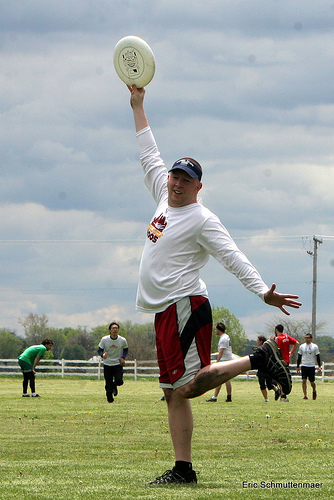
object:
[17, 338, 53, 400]
man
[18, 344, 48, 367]
shirt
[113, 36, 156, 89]
frisbee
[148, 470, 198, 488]
shoe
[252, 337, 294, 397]
shoe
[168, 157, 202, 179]
visor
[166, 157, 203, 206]
head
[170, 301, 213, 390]
shorts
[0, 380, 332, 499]
field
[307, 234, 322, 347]
pole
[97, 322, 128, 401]
man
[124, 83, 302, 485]
man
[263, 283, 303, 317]
hand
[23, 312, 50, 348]
tree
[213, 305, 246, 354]
tree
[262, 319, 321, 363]
tree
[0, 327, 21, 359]
tree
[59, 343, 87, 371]
tree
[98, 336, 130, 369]
shirt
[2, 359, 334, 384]
fence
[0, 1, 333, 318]
sky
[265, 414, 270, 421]
dandelion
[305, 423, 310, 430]
dandelion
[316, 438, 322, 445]
dandelion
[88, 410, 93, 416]
dandelion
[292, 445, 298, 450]
dandelion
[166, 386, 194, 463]
leg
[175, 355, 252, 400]
leg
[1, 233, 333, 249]
power lines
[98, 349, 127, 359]
shirt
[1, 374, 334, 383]
grass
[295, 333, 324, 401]
man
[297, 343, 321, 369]
shirt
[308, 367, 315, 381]
shorts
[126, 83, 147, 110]
hand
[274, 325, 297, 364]
man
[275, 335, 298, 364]
shirt